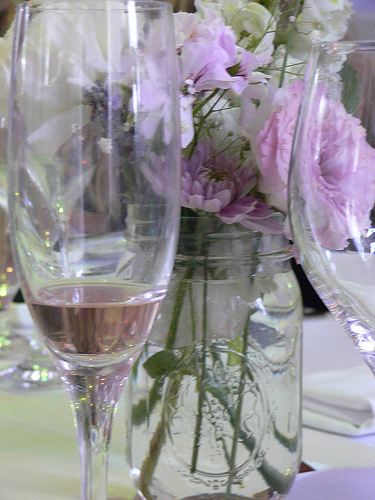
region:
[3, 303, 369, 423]
Three wine glasses are seen.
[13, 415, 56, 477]
Table cloth is white.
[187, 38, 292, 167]
Flowers are white and purple.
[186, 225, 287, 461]
Bottle is filled with water.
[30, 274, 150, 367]
wine is purple color.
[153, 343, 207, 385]
Leaves are green color.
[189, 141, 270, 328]
Flowers are arranged in the bottle.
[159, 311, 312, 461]
One bottle with flowers are seen.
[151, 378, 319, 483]
Bottle is in table.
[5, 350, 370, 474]
Glasses are in table.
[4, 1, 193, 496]
the glass is clear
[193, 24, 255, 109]
the flower is violet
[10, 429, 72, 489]
the table is white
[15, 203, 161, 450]
the glass contains water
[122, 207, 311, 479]
the jar is clear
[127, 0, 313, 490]
the jar contains roses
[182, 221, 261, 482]
the steams are green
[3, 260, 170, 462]
the water is clear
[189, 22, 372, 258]
the flowers are pretty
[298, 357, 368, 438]
the napkin is white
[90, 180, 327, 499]
clear glass mason jar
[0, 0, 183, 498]
wine glass with wine in the bottom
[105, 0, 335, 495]
mason jar filled with flowers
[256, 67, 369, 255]
purple and white flower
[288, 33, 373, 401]
empty wine glass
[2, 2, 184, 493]
clear wine glass with wine left inside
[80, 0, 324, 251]
group of purple and white flowers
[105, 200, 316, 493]
clear mason jar filled with flowers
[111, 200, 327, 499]
clear mason jar with water and flowers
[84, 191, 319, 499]
clear mason jar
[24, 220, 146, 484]
this is a champagne glass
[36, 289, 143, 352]
the glass has some wine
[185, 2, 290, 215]
these are some flowers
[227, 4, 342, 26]
the flowers are white in color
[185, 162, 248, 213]
the flower is violet in color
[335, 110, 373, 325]
the glass is empty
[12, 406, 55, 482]
this is a table cloth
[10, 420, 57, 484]
the table cloth is white in color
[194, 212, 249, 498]
this is a jar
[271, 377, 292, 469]
the jar is made of glass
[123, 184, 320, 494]
glass jar filled with water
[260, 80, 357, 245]
purple flower in jar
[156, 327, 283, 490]
design embossed on jar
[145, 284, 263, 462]
green flower stems in water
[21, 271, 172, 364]
champagne in bottom of glass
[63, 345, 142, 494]
stem on champagne glass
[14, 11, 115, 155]
white flower behind glass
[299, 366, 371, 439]
folded white napkin on table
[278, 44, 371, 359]
empty glass on table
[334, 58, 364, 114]
green leaf amongst flowers